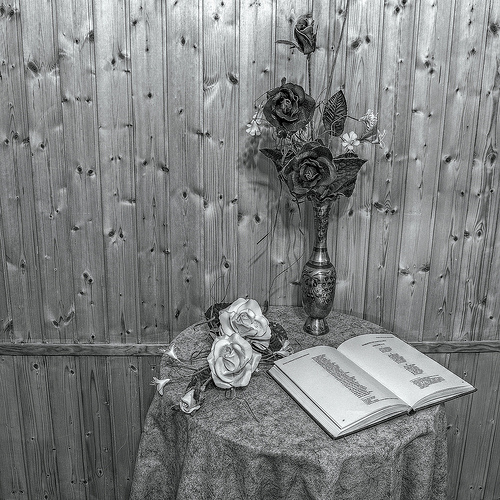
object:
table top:
[158, 303, 444, 457]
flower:
[262, 83, 316, 132]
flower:
[280, 139, 335, 203]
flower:
[294, 13, 319, 56]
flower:
[341, 131, 360, 151]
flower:
[245, 119, 261, 136]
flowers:
[215, 296, 272, 350]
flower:
[205, 332, 263, 389]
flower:
[360, 108, 378, 133]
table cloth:
[128, 306, 449, 497]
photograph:
[2, 1, 493, 498]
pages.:
[335, 333, 471, 409]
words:
[314, 357, 316, 360]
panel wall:
[0, 0, 499, 497]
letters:
[339, 380, 341, 382]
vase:
[301, 207, 338, 337]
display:
[243, 16, 383, 338]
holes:
[76, 165, 83, 174]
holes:
[85, 168, 95, 177]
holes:
[40, 143, 45, 150]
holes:
[147, 91, 153, 100]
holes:
[220, 139, 224, 144]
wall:
[2, 0, 499, 497]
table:
[131, 305, 447, 500]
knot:
[149, 245, 156, 254]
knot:
[220, 255, 233, 273]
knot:
[420, 262, 431, 274]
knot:
[473, 293, 488, 310]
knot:
[18, 255, 27, 276]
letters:
[411, 372, 413, 373]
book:
[266, 332, 477, 442]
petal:
[179, 402, 200, 414]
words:
[354, 378, 357, 381]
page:
[272, 345, 412, 428]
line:
[4, 342, 169, 355]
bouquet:
[245, 17, 378, 207]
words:
[325, 363, 327, 365]